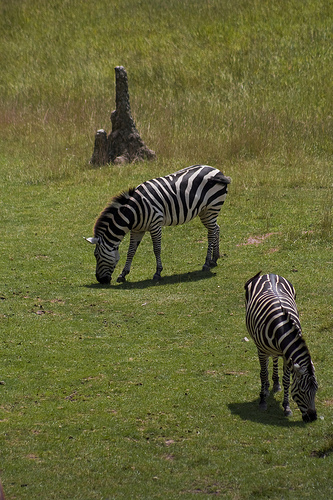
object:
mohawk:
[89, 183, 139, 245]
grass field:
[13, 319, 148, 386]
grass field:
[241, 12, 332, 81]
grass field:
[267, 171, 331, 238]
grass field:
[9, 5, 97, 51]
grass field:
[27, 67, 86, 197]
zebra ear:
[83, 233, 97, 244]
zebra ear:
[286, 353, 293, 371]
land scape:
[1, 3, 328, 494]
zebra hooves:
[279, 396, 291, 417]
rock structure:
[92, 62, 158, 163]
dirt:
[244, 230, 278, 247]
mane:
[85, 191, 139, 215]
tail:
[209, 172, 232, 184]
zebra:
[84, 165, 233, 284]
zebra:
[243, 268, 318, 422]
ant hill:
[79, 59, 163, 170]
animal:
[84, 162, 234, 279]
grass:
[57, 321, 140, 406]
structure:
[90, 62, 157, 166]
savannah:
[6, 7, 331, 471]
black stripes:
[122, 203, 131, 221]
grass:
[54, 147, 327, 450]